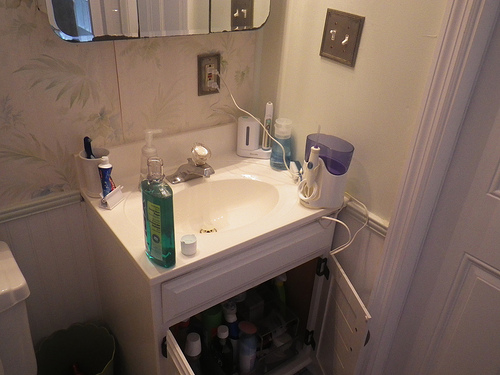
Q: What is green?
A: Liquid in the bottle.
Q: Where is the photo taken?
A: The bathroom.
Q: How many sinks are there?
A: One.